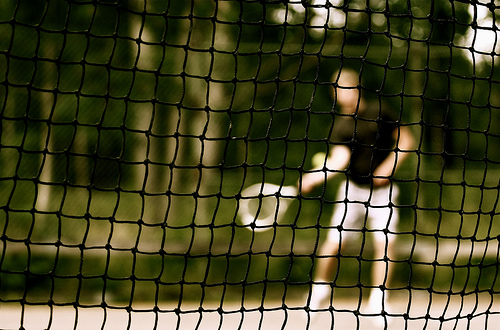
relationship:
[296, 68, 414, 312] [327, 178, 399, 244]
player wearing shorts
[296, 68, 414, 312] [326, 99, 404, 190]
player wearing shirt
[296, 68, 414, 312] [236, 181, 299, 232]
player holding tennis racket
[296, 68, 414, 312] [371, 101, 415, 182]
player has left arm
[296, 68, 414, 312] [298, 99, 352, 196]
player has right arm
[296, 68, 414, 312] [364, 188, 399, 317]
player has left leg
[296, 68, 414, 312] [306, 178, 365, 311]
player has right leg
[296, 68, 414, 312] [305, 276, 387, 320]
player has shoes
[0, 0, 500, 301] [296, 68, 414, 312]
trees behind player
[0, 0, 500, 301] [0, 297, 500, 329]
trees behind tennis court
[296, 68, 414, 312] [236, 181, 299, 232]
player has tennis racket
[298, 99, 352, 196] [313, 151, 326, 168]
right arm hitting tennis ball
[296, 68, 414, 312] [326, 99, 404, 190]
player has shirt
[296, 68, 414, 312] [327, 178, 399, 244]
player has shorts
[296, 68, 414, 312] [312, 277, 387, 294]
player has socks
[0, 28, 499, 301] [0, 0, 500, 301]
fence in front of trees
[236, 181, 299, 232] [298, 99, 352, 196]
tennis racket in right arm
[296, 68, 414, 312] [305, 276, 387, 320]
player wearing shoes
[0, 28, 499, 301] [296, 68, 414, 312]
fence behind player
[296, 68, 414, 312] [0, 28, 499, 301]
player behind fence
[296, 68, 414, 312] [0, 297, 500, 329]
player above tennis court